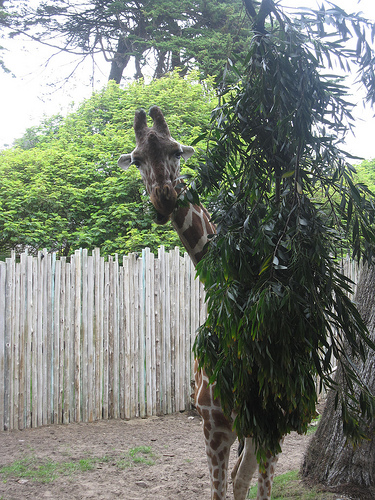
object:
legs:
[200, 413, 240, 498]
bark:
[108, 22, 153, 81]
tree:
[167, 0, 243, 91]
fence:
[0, 243, 367, 430]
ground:
[0, 410, 327, 498]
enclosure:
[1, 247, 374, 499]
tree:
[0, 142, 103, 260]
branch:
[244, 0, 281, 211]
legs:
[250, 407, 287, 498]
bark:
[299, 236, 375, 499]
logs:
[18, 253, 28, 431]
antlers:
[149, 105, 172, 135]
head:
[117, 105, 197, 227]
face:
[135, 128, 185, 225]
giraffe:
[116, 103, 292, 498]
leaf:
[326, 35, 349, 46]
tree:
[103, 0, 176, 84]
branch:
[272, 6, 373, 461]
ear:
[181, 145, 196, 162]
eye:
[173, 150, 183, 160]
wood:
[73, 247, 85, 425]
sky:
[0, 0, 373, 162]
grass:
[0, 443, 155, 489]